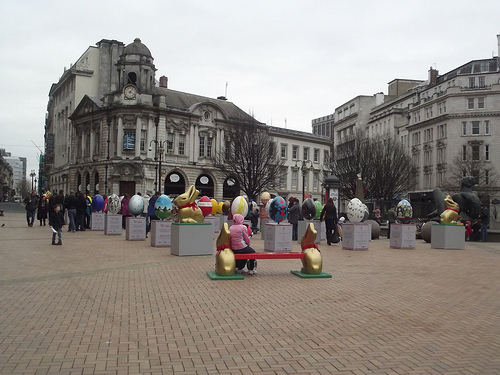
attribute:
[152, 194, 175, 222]
egg — statue, painted, blue, sculpture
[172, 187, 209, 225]
bunny — golden, gold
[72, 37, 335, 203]
building — gray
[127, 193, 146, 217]
egg — white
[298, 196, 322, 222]
egg — black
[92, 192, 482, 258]
group — colorful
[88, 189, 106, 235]
egg — painted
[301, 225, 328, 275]
bunny — golden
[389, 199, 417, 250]
statue — egg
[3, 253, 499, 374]
sidewalk — brick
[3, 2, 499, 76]
sky — white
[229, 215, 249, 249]
jacket — pink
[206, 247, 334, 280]
bench — red